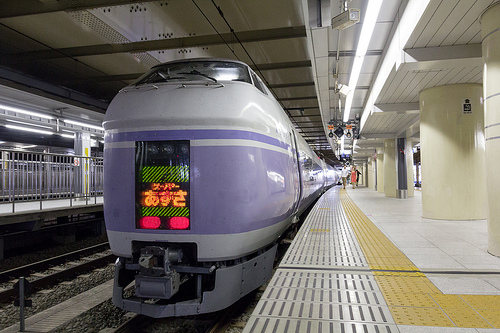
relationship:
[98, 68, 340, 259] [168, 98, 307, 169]
train has stripe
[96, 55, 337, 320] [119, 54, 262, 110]
train has windshield